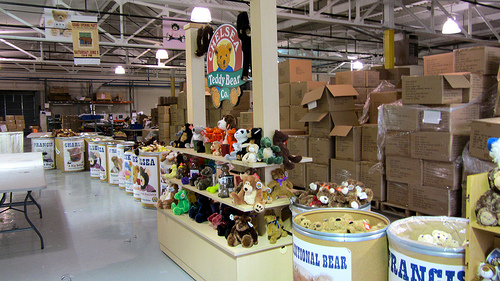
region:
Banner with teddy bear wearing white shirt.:
[41, 5, 73, 40]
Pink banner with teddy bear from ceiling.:
[160, 15, 187, 46]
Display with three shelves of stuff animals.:
[155, 115, 290, 275]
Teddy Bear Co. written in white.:
[207, 68, 238, 98]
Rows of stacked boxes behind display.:
[150, 40, 490, 210]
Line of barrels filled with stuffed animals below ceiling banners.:
[30, 130, 160, 210]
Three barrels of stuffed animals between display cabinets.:
[290, 175, 465, 279]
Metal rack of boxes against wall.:
[40, 70, 130, 120]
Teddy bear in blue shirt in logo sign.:
[205, 40, 242, 105]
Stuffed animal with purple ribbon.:
[269, 166, 296, 199]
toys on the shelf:
[146, 111, 315, 278]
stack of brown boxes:
[320, 39, 497, 212]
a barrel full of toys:
[279, 205, 393, 279]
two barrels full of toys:
[281, 200, 461, 261]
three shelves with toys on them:
[142, 120, 288, 265]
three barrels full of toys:
[272, 165, 459, 272]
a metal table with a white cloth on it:
[0, 138, 49, 255]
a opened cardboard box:
[396, 64, 472, 109]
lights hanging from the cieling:
[85, 33, 190, 103]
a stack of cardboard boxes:
[377, 40, 476, 220]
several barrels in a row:
[42, 122, 170, 213]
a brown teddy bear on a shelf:
[214, 211, 256, 259]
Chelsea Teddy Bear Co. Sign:
[192, 27, 255, 109]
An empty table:
[3, 140, 52, 239]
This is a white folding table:
[6, 144, 54, 239]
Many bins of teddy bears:
[37, 120, 172, 194]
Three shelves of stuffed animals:
[159, 122, 286, 249]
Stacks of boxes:
[284, 58, 470, 207]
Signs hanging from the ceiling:
[47, 3, 192, 69]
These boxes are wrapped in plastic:
[378, 90, 453, 208]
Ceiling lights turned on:
[175, 3, 498, 51]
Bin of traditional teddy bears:
[283, 229, 356, 271]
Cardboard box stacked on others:
[397, 73, 469, 105]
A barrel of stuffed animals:
[290, 206, 387, 279]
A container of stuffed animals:
[53, 135, 87, 170]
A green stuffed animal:
[258, 135, 281, 162]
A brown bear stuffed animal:
[227, 212, 257, 247]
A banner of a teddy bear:
[197, 23, 248, 108]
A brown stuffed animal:
[271, 128, 300, 167]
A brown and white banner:
[70, 15, 100, 64]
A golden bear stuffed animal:
[264, 213, 287, 242]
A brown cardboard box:
[277, 58, 312, 81]